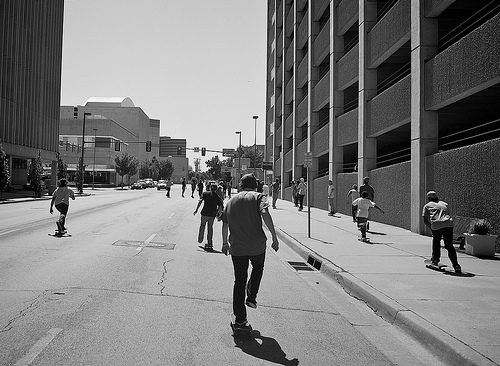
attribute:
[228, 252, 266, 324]
pants — black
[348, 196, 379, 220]
shirt — white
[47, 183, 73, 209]
shirt — white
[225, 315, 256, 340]
skateboard — long, grey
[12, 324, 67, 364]
paint — white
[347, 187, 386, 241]
person — playing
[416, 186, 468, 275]
person — playing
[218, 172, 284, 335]
person — playing